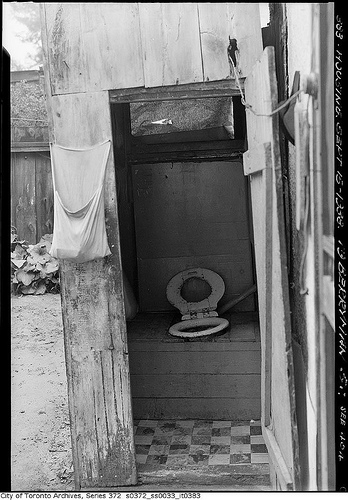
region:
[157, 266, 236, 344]
white dirty toilet seat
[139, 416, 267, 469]
black and white checkered tile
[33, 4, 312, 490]
old outhouse bathroom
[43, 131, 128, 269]
white cloth hanging from wall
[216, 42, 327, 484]
broken outhouse wooden door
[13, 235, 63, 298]
some type of plants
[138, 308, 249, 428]
wooden toilet base with toilet seat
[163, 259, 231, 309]
white toilet lid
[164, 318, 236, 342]
white toilet seat on wooden base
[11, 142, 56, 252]
wooden fence in back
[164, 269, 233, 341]
toilet bowl seat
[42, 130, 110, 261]
bag hanging on door frame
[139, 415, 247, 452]
a dirty checkered floor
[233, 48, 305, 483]
an outhouse wooden door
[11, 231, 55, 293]
plants in a back yard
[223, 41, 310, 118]
a rope connected to the outhouse and the house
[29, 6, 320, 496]
A wooden outhouse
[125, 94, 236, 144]
a window in the out house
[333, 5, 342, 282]
a film strip label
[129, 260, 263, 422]
an old-fashion toilet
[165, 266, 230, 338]
chipped and dirty toilet seat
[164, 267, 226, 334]
toilet seat in an old outhouse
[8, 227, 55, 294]
plant in front of building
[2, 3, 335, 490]
an old black and white photo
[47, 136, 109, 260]
bag hanging on outside wall of outhouse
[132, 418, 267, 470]
checkered style floor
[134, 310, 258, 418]
wooden plank forms a box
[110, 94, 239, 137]
window in the back of the outhouse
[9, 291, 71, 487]
bare ground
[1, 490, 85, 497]
Words "City of Toronto Archives"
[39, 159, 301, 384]
an outhouse with a dirty toilet seat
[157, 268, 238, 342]
this toilet seat looks beat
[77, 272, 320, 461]
this commode is old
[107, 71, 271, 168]
the area over this seat is old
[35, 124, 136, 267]
some bag is on the outhouse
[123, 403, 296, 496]
a dirty checkered floor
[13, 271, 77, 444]
dirt near the shed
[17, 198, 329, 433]
this photo is in black and white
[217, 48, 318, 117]
a string on the outhouse door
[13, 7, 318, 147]
this area is dirty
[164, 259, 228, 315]
The top lid of a toilet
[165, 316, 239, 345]
The bottom of a toilet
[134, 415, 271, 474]
The checkered floor of a toilet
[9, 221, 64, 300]
A group of flowers to the side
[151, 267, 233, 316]
The upper portion of a toilet seat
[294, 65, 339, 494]
A door handle on the side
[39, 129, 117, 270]
A hanging white bag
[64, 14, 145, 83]
The top half of a board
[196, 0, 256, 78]
The right half of a board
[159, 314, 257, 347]
The bottom portion of a toilet seat